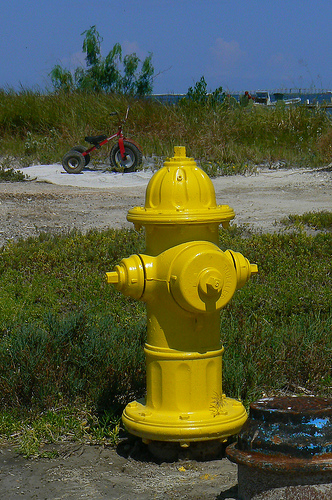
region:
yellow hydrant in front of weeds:
[101, 135, 268, 448]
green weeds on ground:
[29, 306, 91, 401]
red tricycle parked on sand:
[58, 104, 147, 177]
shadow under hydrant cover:
[140, 222, 224, 253]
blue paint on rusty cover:
[283, 409, 329, 439]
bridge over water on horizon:
[271, 82, 321, 97]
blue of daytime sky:
[267, 15, 311, 49]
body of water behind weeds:
[160, 93, 235, 106]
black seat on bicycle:
[83, 129, 109, 147]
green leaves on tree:
[90, 45, 144, 83]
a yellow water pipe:
[130, 295, 256, 455]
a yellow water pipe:
[161, 324, 220, 462]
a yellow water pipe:
[191, 348, 233, 495]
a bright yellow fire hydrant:
[103, 139, 268, 451]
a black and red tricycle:
[61, 104, 141, 171]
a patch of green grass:
[7, 220, 330, 420]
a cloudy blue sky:
[7, 2, 330, 95]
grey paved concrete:
[2, 428, 237, 493]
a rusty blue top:
[226, 390, 330, 471]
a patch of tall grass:
[2, 100, 329, 164]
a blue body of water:
[142, 92, 328, 104]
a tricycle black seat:
[82, 131, 103, 145]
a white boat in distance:
[252, 88, 300, 106]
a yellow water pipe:
[150, 202, 276, 492]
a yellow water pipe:
[155, 305, 203, 414]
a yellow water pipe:
[152, 352, 200, 457]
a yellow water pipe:
[182, 360, 218, 449]